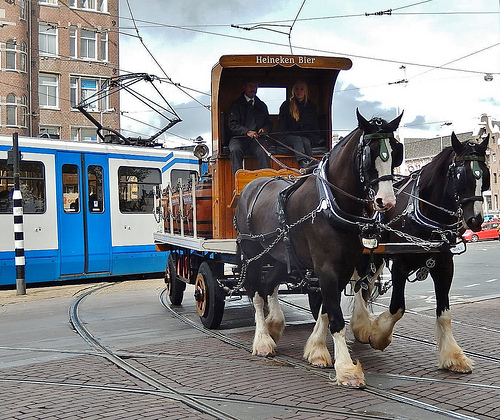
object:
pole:
[12, 132, 26, 293]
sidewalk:
[1, 278, 482, 418]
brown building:
[0, 0, 122, 142]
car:
[460, 221, 500, 242]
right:
[273, 0, 500, 420]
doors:
[59, 153, 84, 277]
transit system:
[0, 74, 197, 293]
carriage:
[149, 53, 494, 393]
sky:
[346, 63, 500, 118]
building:
[332, 113, 500, 214]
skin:
[317, 229, 342, 256]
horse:
[215, 114, 407, 396]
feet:
[328, 352, 368, 389]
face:
[357, 117, 400, 213]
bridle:
[363, 173, 395, 189]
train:
[0, 107, 210, 281]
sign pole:
[2, 129, 34, 296]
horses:
[361, 129, 493, 374]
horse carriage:
[202, 44, 353, 241]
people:
[275, 79, 322, 168]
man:
[227, 78, 273, 174]